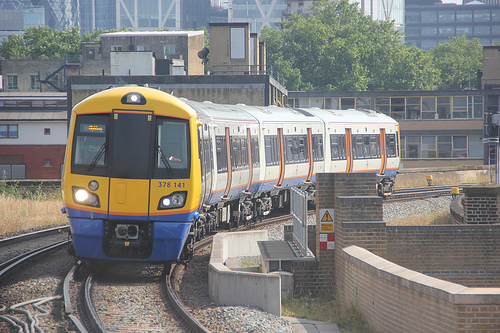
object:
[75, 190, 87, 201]
light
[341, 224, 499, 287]
wall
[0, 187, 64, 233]
grass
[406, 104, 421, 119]
window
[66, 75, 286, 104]
building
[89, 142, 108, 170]
wiper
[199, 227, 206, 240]
wheel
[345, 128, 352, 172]
door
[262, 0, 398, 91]
tree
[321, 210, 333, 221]
sign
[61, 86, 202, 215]
yellow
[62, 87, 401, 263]
train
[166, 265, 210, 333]
tracks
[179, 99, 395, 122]
gray